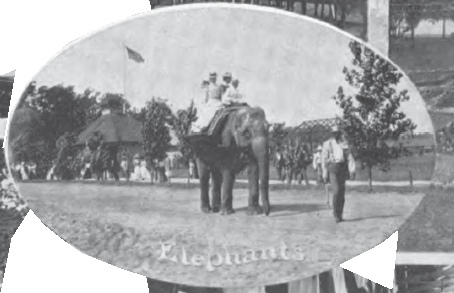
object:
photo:
[0, 0, 443, 291]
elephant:
[179, 97, 284, 219]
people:
[220, 77, 251, 107]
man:
[316, 123, 360, 226]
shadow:
[232, 202, 338, 218]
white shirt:
[318, 138, 355, 163]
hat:
[329, 123, 345, 135]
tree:
[330, 39, 420, 195]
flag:
[119, 42, 149, 64]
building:
[67, 108, 173, 180]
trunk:
[250, 133, 273, 218]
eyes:
[241, 128, 255, 140]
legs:
[216, 167, 238, 218]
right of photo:
[373, 56, 440, 243]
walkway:
[135, 191, 194, 218]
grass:
[113, 212, 162, 234]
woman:
[220, 78, 248, 106]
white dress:
[226, 95, 238, 101]